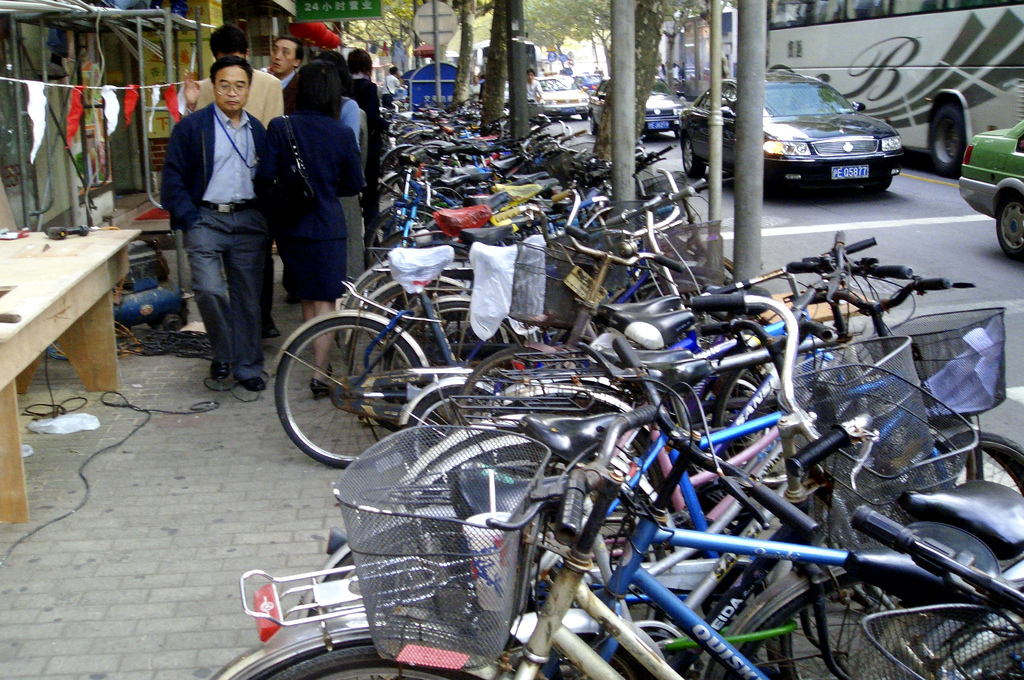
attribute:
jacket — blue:
[152, 102, 271, 245]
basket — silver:
[320, 422, 570, 658]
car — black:
[666, 42, 902, 214]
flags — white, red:
[12, 72, 222, 153]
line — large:
[226, 60, 1006, 676]